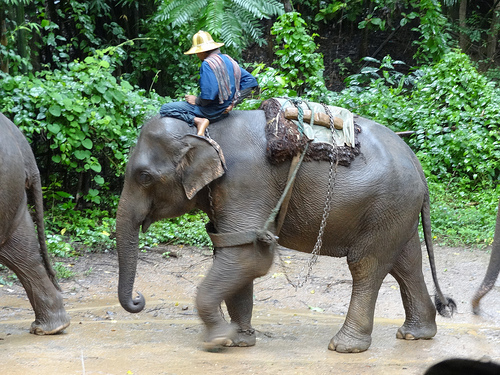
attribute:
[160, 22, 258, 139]
man — sitting, riding, wearing blue, barefoot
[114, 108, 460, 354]
elephant — walking, gray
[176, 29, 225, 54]
hat — safari, straw, yellow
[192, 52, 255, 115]
shirt — blue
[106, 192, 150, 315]
trunk — curled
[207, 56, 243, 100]
scarf — around neck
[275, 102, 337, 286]
chain — silver, securing, hanging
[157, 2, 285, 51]
tree — tropical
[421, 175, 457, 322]
tail — long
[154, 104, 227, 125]
pants — blue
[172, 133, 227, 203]
ear — large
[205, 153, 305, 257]
harness — leather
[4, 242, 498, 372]
mud — being walked in, wet, dirt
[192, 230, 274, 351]
feet — chained